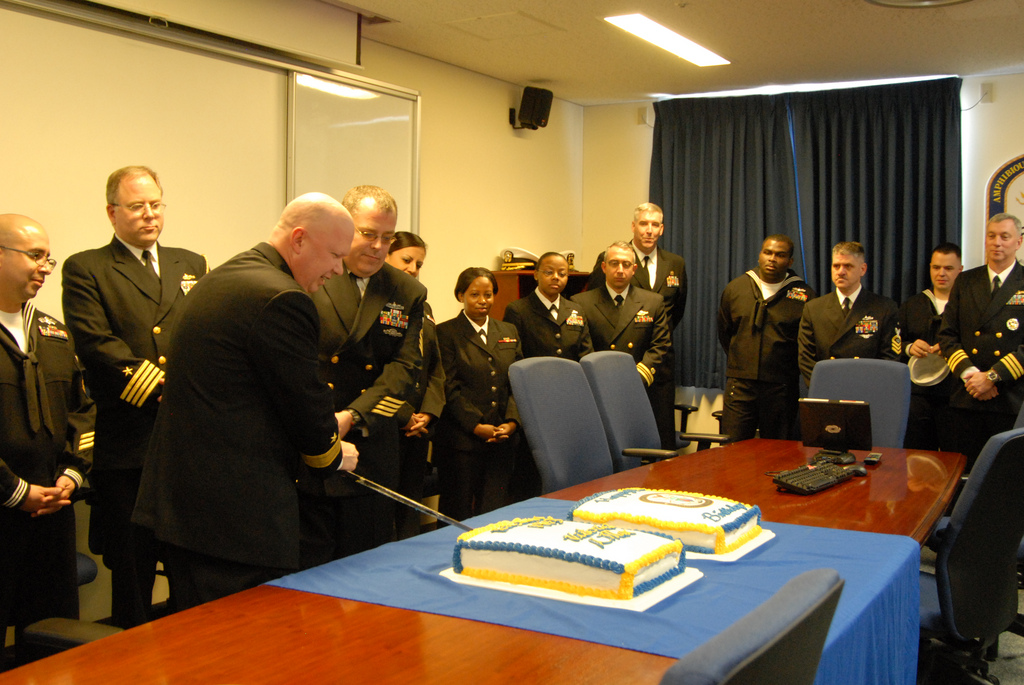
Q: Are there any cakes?
A: Yes, there is a cake.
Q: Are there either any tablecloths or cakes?
A: Yes, there is a cake.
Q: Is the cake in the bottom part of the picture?
A: Yes, the cake is in the bottom of the image.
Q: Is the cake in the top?
A: No, the cake is in the bottom of the image.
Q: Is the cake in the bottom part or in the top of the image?
A: The cake is in the bottom of the image.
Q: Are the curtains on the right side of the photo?
A: Yes, the curtains are on the right of the image.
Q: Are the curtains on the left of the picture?
A: No, the curtains are on the right of the image.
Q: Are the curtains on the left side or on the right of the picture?
A: The curtains are on the right of the image.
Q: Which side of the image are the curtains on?
A: The curtains are on the right of the image.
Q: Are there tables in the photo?
A: Yes, there is a table.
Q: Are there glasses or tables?
A: Yes, there is a table.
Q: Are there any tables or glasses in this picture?
A: Yes, there is a table.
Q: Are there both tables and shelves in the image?
A: No, there is a table but no shelves.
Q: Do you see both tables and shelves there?
A: No, there is a table but no shelves.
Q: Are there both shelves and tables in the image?
A: No, there is a table but no shelves.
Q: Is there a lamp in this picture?
A: No, there are no lamps.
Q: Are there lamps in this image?
A: No, there are no lamps.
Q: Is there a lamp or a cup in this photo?
A: No, there are no lamps or cups.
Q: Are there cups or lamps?
A: No, there are no lamps or cups.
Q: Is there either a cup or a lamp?
A: No, there are no lamps or cups.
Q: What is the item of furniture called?
A: The piece of furniture is a table.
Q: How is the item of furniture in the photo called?
A: The piece of furniture is a table.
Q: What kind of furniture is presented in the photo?
A: The furniture is a table.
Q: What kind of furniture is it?
A: The piece of furniture is a table.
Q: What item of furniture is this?
A: This is a table.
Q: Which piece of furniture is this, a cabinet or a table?
A: This is a table.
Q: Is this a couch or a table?
A: This is a table.